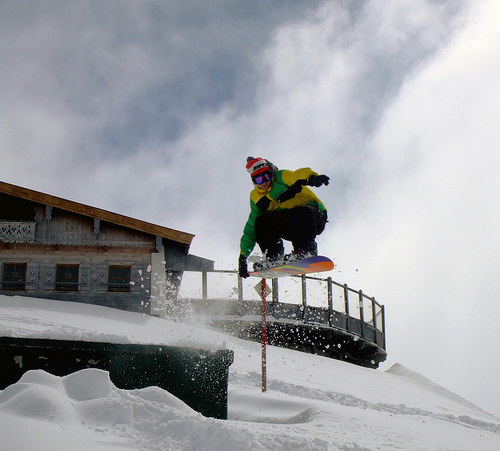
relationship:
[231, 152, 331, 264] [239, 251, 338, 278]
person on snowboard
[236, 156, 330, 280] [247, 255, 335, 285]
person on snowboard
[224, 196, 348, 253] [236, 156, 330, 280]
pants on person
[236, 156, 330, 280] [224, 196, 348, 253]
person wearing pants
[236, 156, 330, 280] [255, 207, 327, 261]
person wearing pants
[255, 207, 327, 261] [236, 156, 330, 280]
pants are on person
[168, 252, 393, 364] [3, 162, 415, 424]
patio on building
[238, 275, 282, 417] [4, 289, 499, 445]
sign in snow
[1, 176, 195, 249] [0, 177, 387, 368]
roof on building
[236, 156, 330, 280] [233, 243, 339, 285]
person on board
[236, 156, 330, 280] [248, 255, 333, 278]
person on board